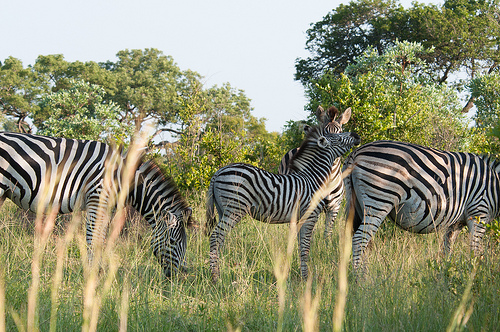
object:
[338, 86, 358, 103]
leaves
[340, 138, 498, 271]
zebra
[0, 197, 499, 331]
grass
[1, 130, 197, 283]
zebra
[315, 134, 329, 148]
ear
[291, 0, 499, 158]
tree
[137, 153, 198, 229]
mane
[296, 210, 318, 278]
leg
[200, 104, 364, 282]
zebra